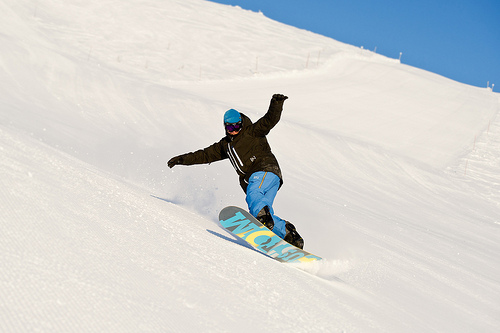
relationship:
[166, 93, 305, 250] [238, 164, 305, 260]
person wearing pants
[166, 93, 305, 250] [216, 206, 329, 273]
person riding snowboard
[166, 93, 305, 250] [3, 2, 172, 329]
person riding in snow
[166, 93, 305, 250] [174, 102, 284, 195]
person wearing coat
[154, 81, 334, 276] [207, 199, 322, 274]
person balancing as they ski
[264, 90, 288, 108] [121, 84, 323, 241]
glove on person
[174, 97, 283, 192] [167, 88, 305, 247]
coat on person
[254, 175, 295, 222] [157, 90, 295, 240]
pants on person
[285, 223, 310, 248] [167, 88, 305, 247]
boot on person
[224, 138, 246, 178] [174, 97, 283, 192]
stripes on front of coat